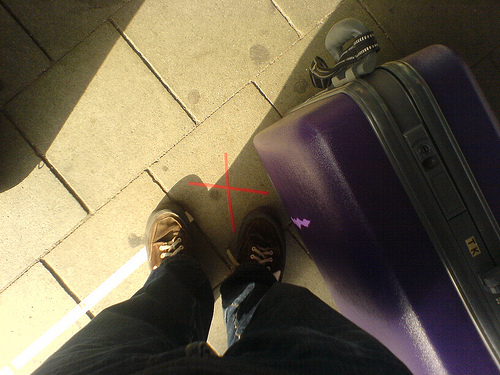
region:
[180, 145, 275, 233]
red x on the floor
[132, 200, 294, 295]
brown shoes with white laces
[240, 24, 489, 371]
a large purple suitcase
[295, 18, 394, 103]
part of a suitcase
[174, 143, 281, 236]
red x next to shoes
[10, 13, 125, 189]
shadow on the floor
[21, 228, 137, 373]
reflection of light on floor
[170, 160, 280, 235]
Red x on the ground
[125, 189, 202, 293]
Brown tennis shoe on a foot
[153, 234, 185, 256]
White laces on a brown shoe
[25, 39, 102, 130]
Shadow on the floor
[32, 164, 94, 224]
Space between tiles on the floor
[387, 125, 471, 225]
Metal fastener on a suitcase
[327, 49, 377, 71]
Purple ribbon on a handle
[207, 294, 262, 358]
Sun on the leg of pants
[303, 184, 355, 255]
Side of a purple suitcase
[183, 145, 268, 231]
the red X on the ground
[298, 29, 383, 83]
the black strap on the bags handle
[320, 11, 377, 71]
thge grey handle of the luggage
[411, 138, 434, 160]
the key hole on the luggage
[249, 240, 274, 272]
the laces on the shoe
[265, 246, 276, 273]
the hole for the laces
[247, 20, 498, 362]
the purple luggage bag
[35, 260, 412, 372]
the jeans on the mans legs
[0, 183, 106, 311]
the bricks on the ground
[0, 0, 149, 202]
the black shadow on the ground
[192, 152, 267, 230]
Red "X" drawn on the ground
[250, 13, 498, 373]
Purple plastic suitcase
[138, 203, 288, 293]
Pair of brown shoes with white laces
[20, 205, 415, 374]
Person wearing blue jean pants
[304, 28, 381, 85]
Black and white strap on a handle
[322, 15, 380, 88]
Gray handle of a suitcase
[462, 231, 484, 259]
Two letter stickers on a suitcase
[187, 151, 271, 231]
Red "X" near a person's feet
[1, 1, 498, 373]
Light brown cement floor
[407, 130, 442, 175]
Key lock of a suitcase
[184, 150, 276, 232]
red x on floor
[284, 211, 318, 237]
lightening bolt on side of suitcase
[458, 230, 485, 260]
initials t k on suitcase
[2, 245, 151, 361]
white stripe on ground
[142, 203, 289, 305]
pair of brown shoes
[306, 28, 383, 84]
black strap on suitcase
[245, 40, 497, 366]
large suitcase on ground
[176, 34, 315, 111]
spots on the floor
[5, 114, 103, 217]
grout is missing between tiles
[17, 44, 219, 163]
cement tiled walkway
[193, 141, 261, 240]
an x on the ground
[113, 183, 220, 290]
a shoe on teh foot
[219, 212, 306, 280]
a shoe on teh foot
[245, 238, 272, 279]
shoe laces on the shoe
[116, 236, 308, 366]
pants on the man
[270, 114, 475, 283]
a purple suitcase on the floor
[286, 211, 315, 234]
white mark on purple suitcase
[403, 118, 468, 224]
lock on purple suitcase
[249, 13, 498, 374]
hard shell purple suitcase on floor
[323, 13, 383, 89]
grey handle on purple suitcase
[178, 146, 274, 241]
red x on floor in front of brown sneakers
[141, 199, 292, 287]
top of a pair of brown sneakers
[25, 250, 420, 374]
pair of blue jeans on person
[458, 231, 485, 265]
letters t and k on top of suitcase